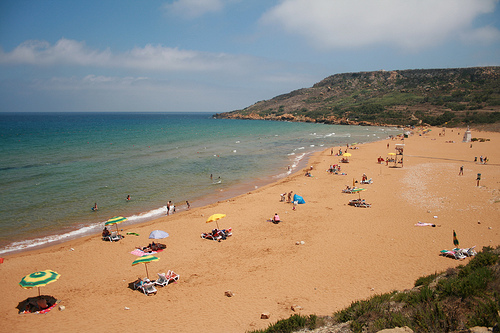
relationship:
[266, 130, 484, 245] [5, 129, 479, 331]
people on beach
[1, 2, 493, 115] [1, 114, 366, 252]
sky above water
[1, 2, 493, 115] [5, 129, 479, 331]
sky above beach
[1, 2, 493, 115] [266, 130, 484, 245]
sky above people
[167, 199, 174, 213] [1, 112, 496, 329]
person on beach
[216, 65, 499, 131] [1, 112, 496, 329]
cliff behind beach